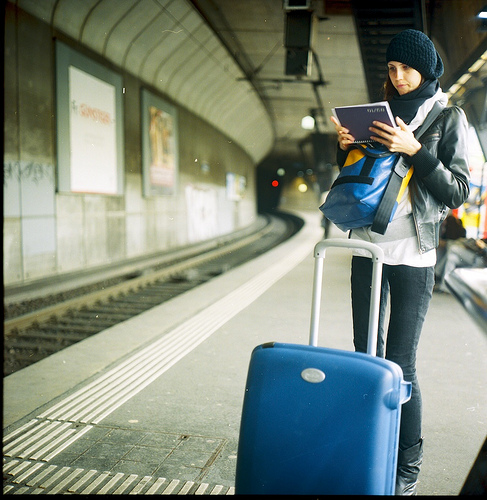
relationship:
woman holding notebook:
[331, 26, 486, 499] [327, 100, 403, 149]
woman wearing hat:
[331, 26, 486, 499] [384, 26, 440, 80]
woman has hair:
[331, 26, 486, 499] [381, 74, 397, 104]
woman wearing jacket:
[331, 26, 486, 499] [335, 102, 471, 252]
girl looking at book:
[331, 26, 486, 499] [327, 100, 403, 149]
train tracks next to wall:
[0, 209, 304, 387] [1, 0, 278, 293]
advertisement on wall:
[69, 65, 119, 201] [1, 0, 278, 293]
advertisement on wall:
[147, 104, 176, 191] [1, 0, 278, 293]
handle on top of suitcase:
[309, 236, 383, 359] [232, 238, 415, 500]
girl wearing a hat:
[331, 26, 486, 499] [384, 26, 440, 80]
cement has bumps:
[1, 210, 486, 497] [2, 207, 327, 500]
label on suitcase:
[300, 366, 327, 385] [232, 238, 415, 500]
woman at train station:
[331, 26, 486, 499] [1, 0, 487, 499]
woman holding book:
[331, 26, 486, 499] [327, 100, 403, 149]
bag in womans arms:
[320, 140, 415, 234] [331, 103, 473, 207]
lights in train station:
[300, 115, 318, 131] [1, 0, 487, 499]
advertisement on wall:
[69, 65, 116, 194] [1, 0, 278, 293]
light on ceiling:
[300, 115, 318, 131] [192, 2, 486, 158]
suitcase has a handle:
[232, 342, 414, 500] [309, 236, 383, 359]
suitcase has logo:
[232, 342, 414, 500] [300, 366, 327, 385]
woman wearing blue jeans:
[331, 26, 486, 499] [353, 248, 435, 449]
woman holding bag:
[331, 26, 486, 499] [320, 140, 415, 234]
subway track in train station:
[0, 209, 304, 387] [1, 0, 487, 499]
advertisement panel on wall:
[42, 30, 250, 211] [1, 0, 278, 293]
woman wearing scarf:
[331, 26, 486, 499] [383, 76, 443, 127]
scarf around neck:
[383, 76, 443, 127] [393, 89, 432, 107]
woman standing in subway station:
[331, 26, 486, 499] [1, 0, 487, 499]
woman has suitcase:
[331, 26, 486, 499] [232, 342, 414, 500]